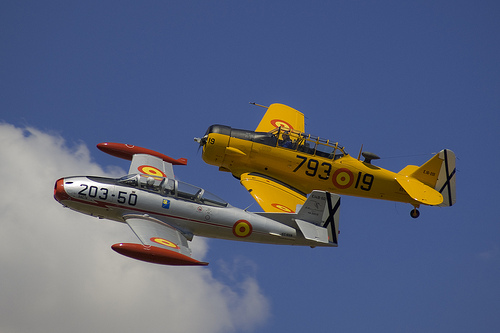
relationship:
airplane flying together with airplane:
[53, 141, 343, 267] [192, 101, 457, 219]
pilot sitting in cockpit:
[142, 175, 155, 191] [119, 173, 228, 208]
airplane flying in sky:
[53, 141, 343, 267] [0, 0, 499, 333]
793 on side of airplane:
[291, 153, 333, 182] [192, 101, 457, 219]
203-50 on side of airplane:
[77, 182, 138, 207] [53, 141, 343, 267]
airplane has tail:
[53, 141, 343, 267] [297, 190, 342, 250]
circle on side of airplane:
[231, 220, 254, 239] [53, 141, 343, 267]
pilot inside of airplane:
[280, 130, 293, 148] [192, 101, 457, 219]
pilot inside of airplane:
[142, 175, 155, 191] [53, 141, 343, 267]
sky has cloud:
[0, 0, 499, 333] [0, 121, 271, 332]